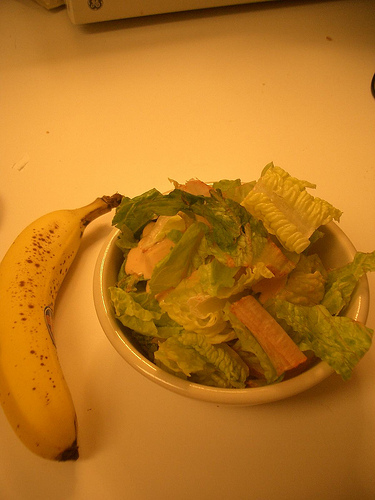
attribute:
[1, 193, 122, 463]
banana — ripening, curved, large, yellow, ripped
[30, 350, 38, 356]
spot — brown, dark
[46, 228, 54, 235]
spot — brown, dark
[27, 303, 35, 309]
spot — brown, dark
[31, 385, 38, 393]
spot — brown, dark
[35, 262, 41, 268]
spot — brown, dark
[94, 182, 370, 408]
bowl — white, circular, ceramic, light-colored, curved, round, yellow, salad, glass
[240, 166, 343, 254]
lettuce — green, curled, bite-sized, veined, ruffled, small, large, light green, in pieces, romaine, yellow colored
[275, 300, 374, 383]
lettuce — green, bite-sized, veined, browning, ruffled, small, in pieces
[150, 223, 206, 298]
lettuce — green, bite-sized, veined, ruffled, small, in pieces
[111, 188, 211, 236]
lettuce — green, bite-sized, veined, ruffled, small, large, dark green, in pieces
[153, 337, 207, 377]
lettuce — green, bite-sized, veined, ruffled, small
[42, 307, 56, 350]
sticker — label, sliver, logo, yellow, company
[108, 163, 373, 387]
food — green, lettuce, salad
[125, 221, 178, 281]
salad dressing — concentrated, small, orange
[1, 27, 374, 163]
surface — flat, table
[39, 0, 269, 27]
appliance — unknown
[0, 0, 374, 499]
surface — large, solid, yellow, table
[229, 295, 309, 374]
lettuce — brownish, in pieces, browning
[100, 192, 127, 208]
tip — brown